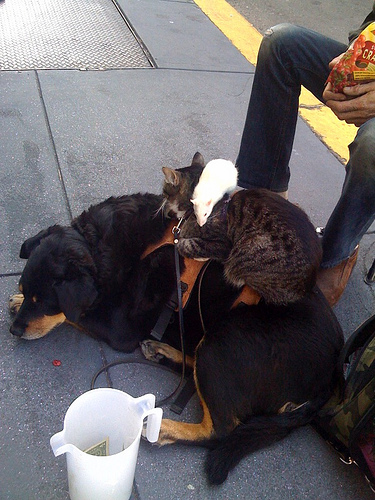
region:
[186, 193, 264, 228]
white rat with pink ears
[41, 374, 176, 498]
money in drink pitcher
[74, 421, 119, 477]
green one dollar bill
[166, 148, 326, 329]
cat with rat on top of him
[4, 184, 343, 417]
dog with cat lying on him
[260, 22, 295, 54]
hole in the man's knee of jeans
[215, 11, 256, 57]
yellow painted line on side of road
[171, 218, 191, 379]
black and silver leash on animal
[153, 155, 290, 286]
a mouse on the cat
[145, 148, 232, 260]
a mouse on the cat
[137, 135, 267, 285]
a mouse on the cat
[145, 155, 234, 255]
a mouse on the cat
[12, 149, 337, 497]
three animals on top of each other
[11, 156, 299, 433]
three animals on top of each other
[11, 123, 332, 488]
three animals on top of each other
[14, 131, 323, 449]
three animals on top of each other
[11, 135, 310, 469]
three animals on top of each other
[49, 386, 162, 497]
A white pitcher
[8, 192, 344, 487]
A dog with dark coat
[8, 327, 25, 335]
Black nose of a dog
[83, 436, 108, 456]
A bill on a white pitcher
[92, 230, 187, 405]
A black leash on a dog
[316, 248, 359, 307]
A brown shoe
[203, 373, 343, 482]
A black tail of a dog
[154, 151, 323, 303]
A cat sitting on top of a dog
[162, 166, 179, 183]
Left ear of a cat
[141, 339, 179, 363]
Right foot of a dog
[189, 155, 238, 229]
a white rat on a cat's back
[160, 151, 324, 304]
a tabby cat on top of a dog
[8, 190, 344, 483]
a black and brown dog laying down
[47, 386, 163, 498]
a white plastic pitcher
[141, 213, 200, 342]
a brown harness on a dog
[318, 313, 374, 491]
a camouflage backpack on the ground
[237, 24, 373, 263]
blue jeans on a man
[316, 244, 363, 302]
a brown boot on a man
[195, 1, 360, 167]
a yellow painted curb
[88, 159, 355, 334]
a rat on a cat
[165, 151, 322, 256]
a white rat on a cat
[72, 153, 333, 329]
a cat on a dog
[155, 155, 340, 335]
a striped cat on a dog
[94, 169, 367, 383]
a cat on a large dog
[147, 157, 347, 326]
a cat wearing a harness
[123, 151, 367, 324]
a cat on a leash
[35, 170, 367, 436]
a dog wearing a harness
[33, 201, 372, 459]
a dog laying on the ground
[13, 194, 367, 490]
a black dog laying on the ground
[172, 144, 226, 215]
a mouse on the cat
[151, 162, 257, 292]
a cat on the dog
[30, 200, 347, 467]
a dog on the sidewalk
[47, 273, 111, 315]
an ear on the animal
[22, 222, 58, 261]
an ear on the animal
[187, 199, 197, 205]
an ear on the animal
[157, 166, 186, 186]
an ear on the animal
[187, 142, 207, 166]
an ear on the animal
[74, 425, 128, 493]
money in a pitcher